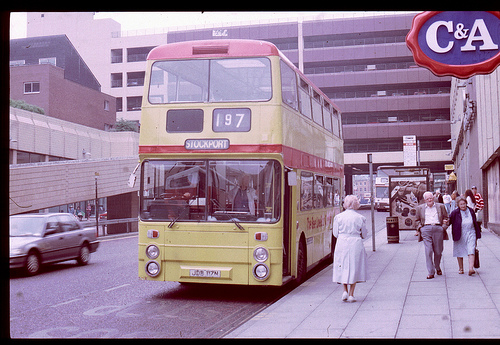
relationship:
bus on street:
[136, 38, 342, 298] [7, 181, 409, 333]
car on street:
[9, 211, 102, 278] [7, 181, 409, 333]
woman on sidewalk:
[330, 194, 367, 301] [224, 213, 499, 342]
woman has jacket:
[330, 194, 367, 301] [331, 211, 367, 286]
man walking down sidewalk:
[418, 191, 445, 278] [224, 213, 499, 342]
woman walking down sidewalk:
[449, 197, 479, 278] [224, 213, 499, 342]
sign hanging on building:
[409, 14, 496, 76] [445, 68, 499, 235]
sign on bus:
[213, 105, 254, 134] [136, 38, 342, 298]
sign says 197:
[213, 105, 254, 134] [215, 112, 247, 127]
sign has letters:
[409, 14, 496, 76] [425, 19, 496, 56]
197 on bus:
[215, 112, 247, 127] [136, 38, 342, 298]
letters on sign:
[425, 19, 496, 56] [409, 14, 496, 76]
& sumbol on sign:
[451, 23, 468, 41] [409, 14, 496, 76]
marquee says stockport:
[185, 139, 230, 148] [187, 141, 227, 148]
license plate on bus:
[189, 269, 222, 279] [136, 38, 342, 298]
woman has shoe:
[330, 194, 367, 301] [341, 291, 349, 302]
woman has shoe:
[330, 194, 367, 301] [349, 293, 358, 305]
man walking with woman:
[418, 191, 445, 278] [449, 197, 479, 278]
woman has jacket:
[449, 197, 479, 278] [449, 204, 482, 242]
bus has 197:
[136, 38, 342, 298] [215, 112, 247, 127]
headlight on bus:
[146, 246, 157, 257] [136, 38, 342, 298]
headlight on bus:
[148, 261, 161, 274] [136, 38, 342, 298]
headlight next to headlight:
[256, 249, 268, 260] [252, 263, 267, 279]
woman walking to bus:
[330, 194, 367, 301] [136, 38, 342, 298]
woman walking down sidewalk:
[330, 194, 367, 301] [224, 213, 499, 342]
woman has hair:
[330, 194, 367, 301] [342, 193, 361, 212]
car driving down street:
[9, 211, 102, 278] [7, 181, 409, 333]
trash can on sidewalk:
[385, 214, 401, 245] [224, 213, 499, 342]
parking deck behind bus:
[28, 14, 451, 208] [136, 38, 342, 298]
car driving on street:
[9, 211, 102, 278] [7, 181, 409, 333]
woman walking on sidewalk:
[330, 194, 367, 301] [224, 213, 499, 342]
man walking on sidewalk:
[418, 191, 445, 278] [224, 213, 499, 342]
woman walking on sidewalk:
[449, 197, 479, 278] [224, 213, 499, 342]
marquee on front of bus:
[185, 139, 230, 148] [136, 38, 342, 298]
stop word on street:
[31, 322, 173, 344] [7, 181, 409, 333]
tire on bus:
[299, 236, 310, 280] [136, 38, 342, 298]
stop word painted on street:
[31, 322, 173, 344] [7, 181, 409, 333]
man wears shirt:
[468, 183, 483, 211] [471, 192, 483, 209]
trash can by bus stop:
[385, 214, 401, 245] [384, 160, 435, 239]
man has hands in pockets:
[418, 191, 445, 278] [418, 224, 445, 237]